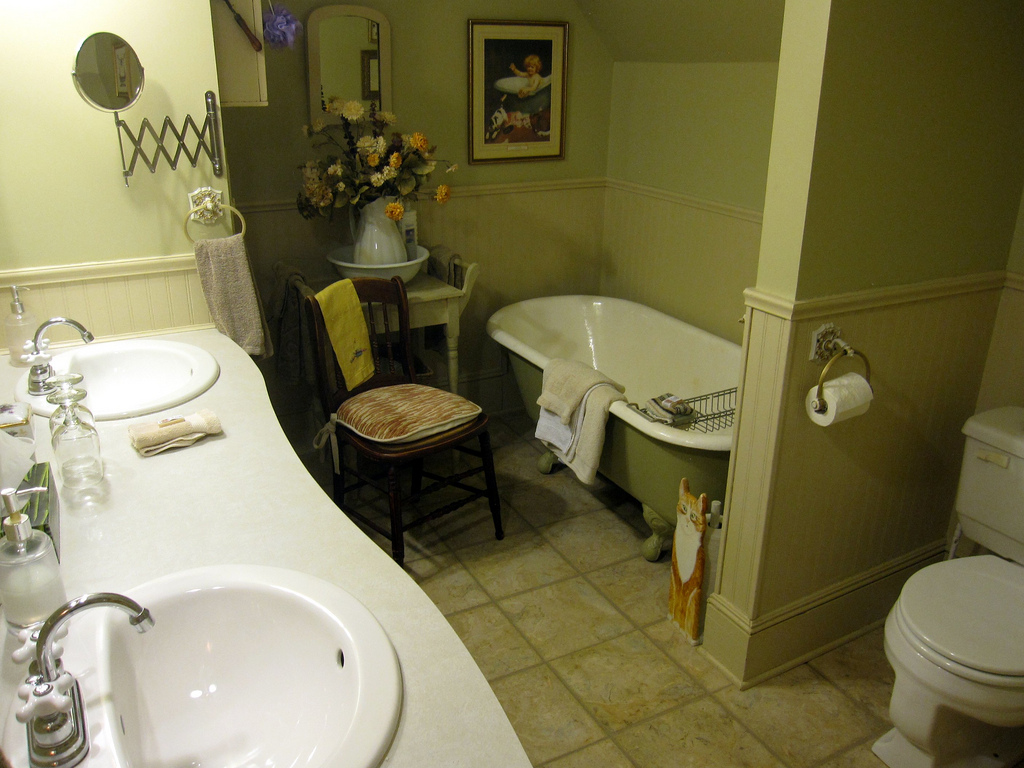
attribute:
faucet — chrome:
[12, 592, 153, 765]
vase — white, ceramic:
[355, 195, 403, 260]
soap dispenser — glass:
[10, 482, 58, 608]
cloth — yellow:
[316, 273, 383, 394]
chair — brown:
[284, 262, 513, 569]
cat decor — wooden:
[660, 469, 719, 658]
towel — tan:
[122, 404, 231, 465]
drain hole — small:
[330, 642, 357, 677]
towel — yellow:
[310, 271, 380, 397]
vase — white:
[345, 188, 412, 271]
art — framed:
[457, 7, 572, 170]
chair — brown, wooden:
[295, 268, 516, 577]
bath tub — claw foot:
[478, 290, 747, 561]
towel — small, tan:
[531, 353, 625, 481]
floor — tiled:
[318, 418, 1019, 762]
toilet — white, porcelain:
[869, 404, 1021, 765]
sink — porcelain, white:
[17, 564, 400, 765]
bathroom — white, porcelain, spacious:
[7, 9, 1021, 764]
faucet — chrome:
[17, 316, 95, 394]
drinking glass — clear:
[48, 389, 103, 482]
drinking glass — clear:
[48, 374, 94, 433]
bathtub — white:
[484, 281, 742, 562]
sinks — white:
[13, 331, 405, 764]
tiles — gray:
[318, 417, 1021, 763]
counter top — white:
[6, 320, 534, 764]